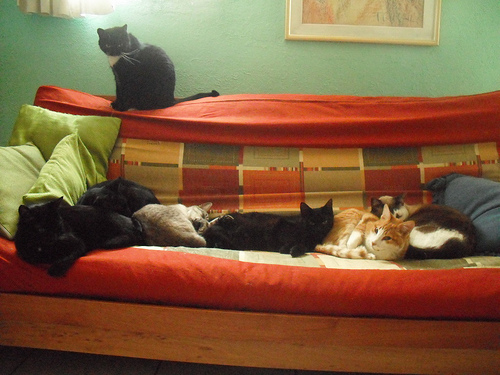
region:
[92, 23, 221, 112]
the black cat on the couch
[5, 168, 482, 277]
the cats laying in a pile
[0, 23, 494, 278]
the cats on the couch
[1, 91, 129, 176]
the green pillows on the couch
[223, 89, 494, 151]
the red blanket on the back of the couch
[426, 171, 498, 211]
the blue pillow on the couch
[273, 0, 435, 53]
the picture on the wall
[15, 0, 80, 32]
the white drapes over the window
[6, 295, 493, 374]
the wooden frame of the couch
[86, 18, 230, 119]
A cat sits on the couch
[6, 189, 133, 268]
A cat lays on the couch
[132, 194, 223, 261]
A cat lays on the couch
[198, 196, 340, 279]
A cat lays on the couch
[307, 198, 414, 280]
A cat lays on the couch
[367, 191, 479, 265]
A cat lays on the couch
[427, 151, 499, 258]
The pillow is blue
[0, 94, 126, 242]
The pillow is green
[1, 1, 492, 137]
curtain and painting hanging on green wall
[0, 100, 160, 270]
black cats at end of sofa next to green pillows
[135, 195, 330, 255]
curled gray cat with paws on black cat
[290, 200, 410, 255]
black cat leaning head on orange and white cat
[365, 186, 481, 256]
black and white cat leaning on back of orange and white cat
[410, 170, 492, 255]
blue pillow next to black and white cat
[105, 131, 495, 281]
futon fabric composed of squares blocks of color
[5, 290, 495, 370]
wooden base under futon seat cushion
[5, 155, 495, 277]
cats lying in a row on a futon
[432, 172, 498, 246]
a navy pillow on a couch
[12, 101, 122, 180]
a green pillow on a couch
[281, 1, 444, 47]
a picture hanging on the wall above a couch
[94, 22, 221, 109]
a black cat on the back of a couch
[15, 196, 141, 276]
a black cat laying next to a green pillow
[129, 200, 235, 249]
a grey cat laying with black cats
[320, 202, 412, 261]
an orange and white cat laying on a couch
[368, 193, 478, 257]
a black and white cat laying on a couch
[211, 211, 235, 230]
the paw of a gray cat on a black cat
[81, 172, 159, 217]
a black cat resting its head on another black cat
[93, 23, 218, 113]
black and white cat on back of futon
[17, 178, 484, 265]
six cats lounging on futon sofa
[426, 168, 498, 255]
gray throw pillow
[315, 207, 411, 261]
orange and white short-haired tabby cat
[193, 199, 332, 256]
all-black cat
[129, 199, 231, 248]
gray cat snuggling between three other cats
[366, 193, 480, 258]
brown and white cat on sofa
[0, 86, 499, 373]
multi-colored futon sofa with wood frame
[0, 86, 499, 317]
orange, brown, tan, yellow, and taupe futon with gold ribbon squares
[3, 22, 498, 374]
six cats together on futon cushion while one solitary cat perches on top frame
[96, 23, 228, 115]
black cat is sitting on the back of the couch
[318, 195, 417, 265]
cat is orange and white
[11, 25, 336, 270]
four cats are black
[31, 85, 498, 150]
cover on the back of the couch is orange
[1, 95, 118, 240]
pillows are green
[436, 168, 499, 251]
pillow is blue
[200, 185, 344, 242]
cat laying down on a couch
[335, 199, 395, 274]
cat laying down on a couch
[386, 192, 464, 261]
cat laying down on a couch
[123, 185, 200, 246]
cat laying down on a couch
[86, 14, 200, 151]
cat sitting on a couch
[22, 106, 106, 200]
green pillow on couch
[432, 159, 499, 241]
black pillow on couch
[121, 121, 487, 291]
checkered blanket covering couch